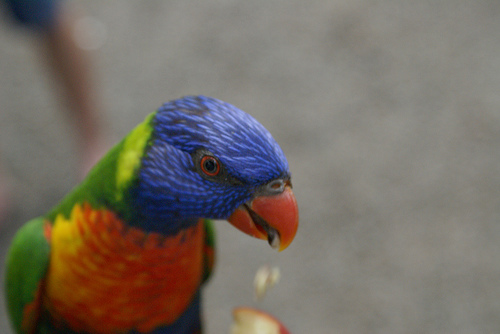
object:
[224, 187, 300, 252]
beak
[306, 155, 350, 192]
ground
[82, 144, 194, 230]
neck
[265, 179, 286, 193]
nostril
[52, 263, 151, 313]
feathers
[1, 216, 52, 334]
green wing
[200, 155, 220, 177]
eye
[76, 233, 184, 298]
breast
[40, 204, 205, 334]
body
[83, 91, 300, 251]
head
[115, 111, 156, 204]
strip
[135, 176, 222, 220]
cheek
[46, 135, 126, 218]
back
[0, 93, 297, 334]
bird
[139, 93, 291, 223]
feathers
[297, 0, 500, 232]
background